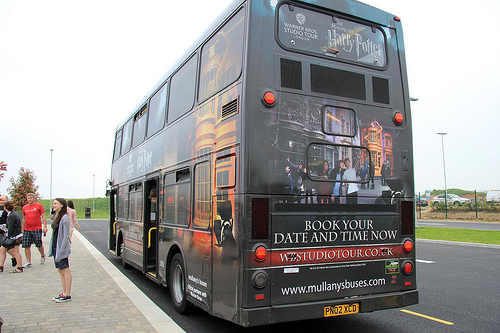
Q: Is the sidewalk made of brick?
A: Yes, the sidewalk is made of brick.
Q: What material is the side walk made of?
A: The side walk is made of brick.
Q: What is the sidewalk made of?
A: The side walk is made of brick.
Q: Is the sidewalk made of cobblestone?
A: No, the sidewalk is made of brick.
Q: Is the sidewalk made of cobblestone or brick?
A: The sidewalk is made of brick.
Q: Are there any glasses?
A: No, there are no glasses.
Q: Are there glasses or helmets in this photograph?
A: No, there are no glasses or helmets.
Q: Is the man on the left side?
A: Yes, the man is on the left of the image.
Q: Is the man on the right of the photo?
A: No, the man is on the left of the image.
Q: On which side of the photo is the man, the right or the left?
A: The man is on the left of the image.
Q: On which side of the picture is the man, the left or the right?
A: The man is on the left of the image.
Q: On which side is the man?
A: The man is on the left of the image.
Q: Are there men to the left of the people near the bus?
A: Yes, there is a man to the left of the people.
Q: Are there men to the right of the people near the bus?
A: No, the man is to the left of the people.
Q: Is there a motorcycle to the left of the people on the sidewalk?
A: No, there is a man to the left of the people.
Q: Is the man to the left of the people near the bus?
A: Yes, the man is to the left of the people.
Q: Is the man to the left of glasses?
A: No, the man is to the left of the people.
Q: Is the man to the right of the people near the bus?
A: No, the man is to the left of the people.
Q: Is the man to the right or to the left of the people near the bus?
A: The man is to the left of the people.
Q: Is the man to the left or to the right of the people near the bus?
A: The man is to the left of the people.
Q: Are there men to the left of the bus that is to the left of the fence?
A: Yes, there is a man to the left of the bus.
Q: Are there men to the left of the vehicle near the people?
A: Yes, there is a man to the left of the bus.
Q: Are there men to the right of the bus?
A: No, the man is to the left of the bus.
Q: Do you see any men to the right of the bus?
A: No, the man is to the left of the bus.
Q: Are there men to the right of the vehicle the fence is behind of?
A: No, the man is to the left of the bus.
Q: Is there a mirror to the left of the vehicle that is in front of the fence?
A: No, there is a man to the left of the bus.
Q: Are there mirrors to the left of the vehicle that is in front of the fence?
A: No, there is a man to the left of the bus.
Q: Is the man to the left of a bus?
A: Yes, the man is to the left of a bus.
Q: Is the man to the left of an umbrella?
A: No, the man is to the left of a bus.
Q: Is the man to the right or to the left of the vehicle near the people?
A: The man is to the left of the bus.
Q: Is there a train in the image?
A: No, there are no trains.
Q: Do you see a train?
A: No, there are no trains.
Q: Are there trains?
A: No, there are no trains.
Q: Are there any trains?
A: No, there are no trains.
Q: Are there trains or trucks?
A: No, there are no trains or trucks.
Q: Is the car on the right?
A: Yes, the car is on the right of the image.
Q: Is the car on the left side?
A: No, the car is on the right of the image.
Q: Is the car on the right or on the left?
A: The car is on the right of the image.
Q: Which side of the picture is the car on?
A: The car is on the right of the image.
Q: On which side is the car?
A: The car is on the right of the image.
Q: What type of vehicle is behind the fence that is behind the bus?
A: The vehicle is a car.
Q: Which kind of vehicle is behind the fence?
A: The vehicle is a car.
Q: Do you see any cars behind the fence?
A: Yes, there is a car behind the fence.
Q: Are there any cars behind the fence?
A: Yes, there is a car behind the fence.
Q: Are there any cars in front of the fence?
A: No, the car is behind the fence.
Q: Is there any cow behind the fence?
A: No, there is a car behind the fence.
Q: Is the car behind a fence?
A: Yes, the car is behind a fence.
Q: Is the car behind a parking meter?
A: No, the car is behind a fence.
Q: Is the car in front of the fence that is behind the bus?
A: No, the car is behind the fence.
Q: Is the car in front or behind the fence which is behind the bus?
A: The car is behind the fence.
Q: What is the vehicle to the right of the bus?
A: The vehicle is a car.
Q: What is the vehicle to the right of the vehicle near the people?
A: The vehicle is a car.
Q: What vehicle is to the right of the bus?
A: The vehicle is a car.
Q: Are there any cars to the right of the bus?
A: Yes, there is a car to the right of the bus.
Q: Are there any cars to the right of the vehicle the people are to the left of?
A: Yes, there is a car to the right of the bus.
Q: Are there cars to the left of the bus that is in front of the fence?
A: No, the car is to the right of the bus.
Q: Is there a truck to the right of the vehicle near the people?
A: No, there is a car to the right of the bus.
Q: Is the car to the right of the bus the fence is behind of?
A: Yes, the car is to the right of the bus.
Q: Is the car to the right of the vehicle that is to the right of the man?
A: Yes, the car is to the right of the bus.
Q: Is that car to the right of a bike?
A: No, the car is to the right of the bus.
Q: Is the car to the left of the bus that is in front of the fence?
A: No, the car is to the right of the bus.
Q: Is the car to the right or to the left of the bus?
A: The car is to the right of the bus.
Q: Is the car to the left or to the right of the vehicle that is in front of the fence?
A: The car is to the right of the bus.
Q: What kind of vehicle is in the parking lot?
A: The vehicle is a car.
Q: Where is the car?
A: The car is in the parking lot.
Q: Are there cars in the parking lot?
A: Yes, there is a car in the parking lot.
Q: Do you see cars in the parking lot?
A: Yes, there is a car in the parking lot.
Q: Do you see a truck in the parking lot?
A: No, there is a car in the parking lot.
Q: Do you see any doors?
A: Yes, there is a door.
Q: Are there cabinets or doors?
A: Yes, there is a door.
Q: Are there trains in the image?
A: No, there are no trains.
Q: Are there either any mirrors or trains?
A: No, there are no trains or mirrors.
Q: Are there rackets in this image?
A: No, there are no rackets.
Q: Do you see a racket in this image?
A: No, there are no rackets.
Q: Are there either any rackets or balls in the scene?
A: No, there are no rackets or balls.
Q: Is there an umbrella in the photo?
A: No, there are no umbrellas.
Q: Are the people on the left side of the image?
A: Yes, the people are on the left of the image.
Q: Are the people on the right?
A: No, the people are on the left of the image.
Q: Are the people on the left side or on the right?
A: The people are on the left of the image.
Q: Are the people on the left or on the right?
A: The people are on the left of the image.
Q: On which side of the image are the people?
A: The people are on the left of the image.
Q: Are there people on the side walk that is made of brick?
A: Yes, there are people on the sidewalk.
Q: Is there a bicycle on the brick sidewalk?
A: No, there are people on the sidewalk.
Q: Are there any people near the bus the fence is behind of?
A: Yes, there are people near the bus.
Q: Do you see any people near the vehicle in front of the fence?
A: Yes, there are people near the bus.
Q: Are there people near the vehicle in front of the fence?
A: Yes, there are people near the bus.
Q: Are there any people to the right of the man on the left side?
A: Yes, there are people to the right of the man.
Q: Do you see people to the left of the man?
A: No, the people are to the right of the man.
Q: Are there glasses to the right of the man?
A: No, there are people to the right of the man.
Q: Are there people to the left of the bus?
A: Yes, there are people to the left of the bus.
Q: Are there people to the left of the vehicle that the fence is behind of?
A: Yes, there are people to the left of the bus.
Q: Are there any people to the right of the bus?
A: No, the people are to the left of the bus.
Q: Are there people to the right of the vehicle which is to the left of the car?
A: No, the people are to the left of the bus.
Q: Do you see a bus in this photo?
A: Yes, there is a bus.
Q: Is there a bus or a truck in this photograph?
A: Yes, there is a bus.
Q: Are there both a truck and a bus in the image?
A: No, there is a bus but no trucks.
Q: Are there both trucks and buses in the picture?
A: No, there is a bus but no trucks.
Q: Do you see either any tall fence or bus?
A: Yes, there is a tall bus.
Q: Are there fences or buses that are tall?
A: Yes, the bus is tall.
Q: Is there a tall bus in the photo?
A: Yes, there is a tall bus.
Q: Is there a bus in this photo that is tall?
A: Yes, there is a bus that is tall.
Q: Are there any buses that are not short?
A: Yes, there is a tall bus.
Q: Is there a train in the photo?
A: No, there are no trains.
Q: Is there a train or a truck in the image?
A: No, there are no trains or trucks.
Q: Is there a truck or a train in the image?
A: No, there are no trains or trucks.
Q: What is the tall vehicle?
A: The vehicle is a bus.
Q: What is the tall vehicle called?
A: The vehicle is a bus.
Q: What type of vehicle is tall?
A: The vehicle is a bus.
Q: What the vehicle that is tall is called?
A: The vehicle is a bus.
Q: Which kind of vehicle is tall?
A: The vehicle is a bus.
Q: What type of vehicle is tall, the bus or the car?
A: The bus is tall.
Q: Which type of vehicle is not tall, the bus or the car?
A: The car is not tall.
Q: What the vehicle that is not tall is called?
A: The vehicle is a car.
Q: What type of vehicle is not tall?
A: The vehicle is a car.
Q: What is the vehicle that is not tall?
A: The vehicle is a car.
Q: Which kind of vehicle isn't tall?
A: The vehicle is a car.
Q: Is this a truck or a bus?
A: This is a bus.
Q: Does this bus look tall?
A: Yes, the bus is tall.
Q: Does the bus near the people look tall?
A: Yes, the bus is tall.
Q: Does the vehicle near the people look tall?
A: Yes, the bus is tall.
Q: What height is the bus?
A: The bus is tall.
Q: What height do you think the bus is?
A: The bus is tall.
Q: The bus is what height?
A: The bus is tall.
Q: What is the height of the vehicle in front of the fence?
A: The bus is tall.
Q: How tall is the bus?
A: The bus is tall.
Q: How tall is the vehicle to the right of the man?
A: The bus is tall.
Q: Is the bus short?
A: No, the bus is tall.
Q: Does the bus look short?
A: No, the bus is tall.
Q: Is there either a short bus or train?
A: No, there is a bus but it is tall.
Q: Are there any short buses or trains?
A: No, there is a bus but it is tall.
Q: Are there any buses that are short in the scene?
A: No, there is a bus but it is tall.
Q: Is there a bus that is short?
A: No, there is a bus but it is tall.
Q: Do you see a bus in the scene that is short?
A: No, there is a bus but it is tall.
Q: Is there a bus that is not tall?
A: No, there is a bus but it is tall.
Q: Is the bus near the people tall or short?
A: The bus is tall.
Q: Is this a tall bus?
A: Yes, this is a tall bus.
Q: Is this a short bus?
A: No, this is a tall bus.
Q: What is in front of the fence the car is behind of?
A: The bus is in front of the fence.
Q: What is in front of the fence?
A: The bus is in front of the fence.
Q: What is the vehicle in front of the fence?
A: The vehicle is a bus.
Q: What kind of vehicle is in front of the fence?
A: The vehicle is a bus.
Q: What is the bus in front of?
A: The bus is in front of the fence.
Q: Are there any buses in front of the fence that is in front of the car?
A: Yes, there is a bus in front of the fence.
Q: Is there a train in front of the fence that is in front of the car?
A: No, there is a bus in front of the fence.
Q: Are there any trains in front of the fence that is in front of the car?
A: No, there is a bus in front of the fence.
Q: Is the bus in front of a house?
A: No, the bus is in front of a fence.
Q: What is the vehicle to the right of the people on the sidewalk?
A: The vehicle is a bus.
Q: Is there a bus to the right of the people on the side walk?
A: Yes, there is a bus to the right of the people.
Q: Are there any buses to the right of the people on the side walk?
A: Yes, there is a bus to the right of the people.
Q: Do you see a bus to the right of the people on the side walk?
A: Yes, there is a bus to the right of the people.